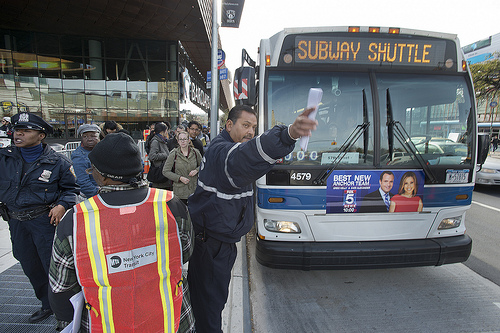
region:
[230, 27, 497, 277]
A blue and white bus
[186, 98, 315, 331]
A man pointing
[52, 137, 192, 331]
A man wearing an orange vest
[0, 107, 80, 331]
A police officer standing on the sidewalk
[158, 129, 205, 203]
A woman wearing a green jacket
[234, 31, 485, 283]
A bus parked next to a sidewalk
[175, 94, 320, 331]
A man wearing a blue jacket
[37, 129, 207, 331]
A man wearing a black hat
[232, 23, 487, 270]
A bus with it's lights on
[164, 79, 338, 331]
A man holding a piece of paper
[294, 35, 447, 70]
A display screen for a bus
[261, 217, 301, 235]
A front right headlight on a bus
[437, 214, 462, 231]
A front left headlight on a bus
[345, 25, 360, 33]
A small orange light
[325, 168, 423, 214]
An advertisement on a bus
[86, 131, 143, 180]
Black knitt cap on a head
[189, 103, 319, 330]
Man wearing a jacket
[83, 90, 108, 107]
A glass window on a building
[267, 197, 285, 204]
A light on the front of a bus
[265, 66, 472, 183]
A windshield on a big bus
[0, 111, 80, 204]
badge on officer's hat and jacket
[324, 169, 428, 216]
man and lady on advertisement sign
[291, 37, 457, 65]
the bus is a shuttle for the subway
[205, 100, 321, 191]
the man is pointing right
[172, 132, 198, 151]
lady wearing eyeglasses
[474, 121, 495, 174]
left outside mirror on bus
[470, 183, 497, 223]
white line in the street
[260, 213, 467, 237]
bus front headlights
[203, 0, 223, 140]
metal pole where people are standing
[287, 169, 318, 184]
number on bus is 4579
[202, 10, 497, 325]
Bus riding down street.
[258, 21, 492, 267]
Bus with big windshield in front.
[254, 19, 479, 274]
Bus with numbers 4579 in window.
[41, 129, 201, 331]
Man wearing orange safety vest.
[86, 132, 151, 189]
Man wearing black hat.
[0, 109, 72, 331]
Police officer wearing uniform.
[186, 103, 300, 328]
Man wearing blue and grey striped jacket.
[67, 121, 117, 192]
Lady wearing grey tam.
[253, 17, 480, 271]
Bus with advertising sign on front.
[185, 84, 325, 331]
Man holding papers in his hand.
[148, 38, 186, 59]
window of a building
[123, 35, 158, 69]
window of a building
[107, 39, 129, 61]
window of a building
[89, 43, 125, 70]
window of a building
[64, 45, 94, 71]
window of a building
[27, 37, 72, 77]
window of a building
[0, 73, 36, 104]
window of a building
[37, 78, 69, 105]
window of a building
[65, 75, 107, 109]
window of a building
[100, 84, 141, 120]
window of a building